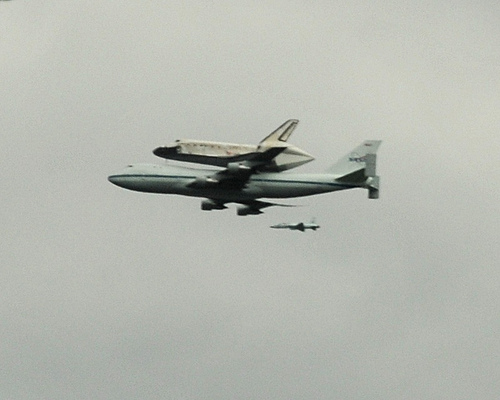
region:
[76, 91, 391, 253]
this is a plane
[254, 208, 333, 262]
this is a smaller plane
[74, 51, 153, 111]
the sky is grey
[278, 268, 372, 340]
the sky is grey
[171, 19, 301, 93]
the sky is grey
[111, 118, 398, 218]
this is a plane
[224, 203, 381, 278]
this is a plane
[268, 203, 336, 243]
this plane is a small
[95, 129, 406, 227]
this plane is a big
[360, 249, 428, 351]
the sky is gray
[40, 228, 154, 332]
the sky is gray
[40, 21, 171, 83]
the sky is gray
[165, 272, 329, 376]
the sky is gray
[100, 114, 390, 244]
3 planes in the air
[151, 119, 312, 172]
white and black plane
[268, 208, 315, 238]
small plane in the distance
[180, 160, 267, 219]
engines on the largest plane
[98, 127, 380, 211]
blue and gray plane with smaller plane on top of it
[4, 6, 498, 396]
clear skies the planes are flying in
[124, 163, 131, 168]
cockpit windows of largest plane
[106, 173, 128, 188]
nose of the largest plane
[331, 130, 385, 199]
tail wings of the largest plane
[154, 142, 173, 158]
black nose of white and black plane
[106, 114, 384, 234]
several vehicles in air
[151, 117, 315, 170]
nasa space shuttle is black and white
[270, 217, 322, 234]
jet flying escort beside planes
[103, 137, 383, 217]
large airplane under shuttle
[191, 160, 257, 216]
four turbine engines on plane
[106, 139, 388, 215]
large plane is grey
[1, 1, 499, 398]
sky is overcast and grey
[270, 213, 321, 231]
airforce is light gray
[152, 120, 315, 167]
space shuttle is black and white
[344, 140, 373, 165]
nasa insignia on tail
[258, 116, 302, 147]
white part on plane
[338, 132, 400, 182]
white part on plane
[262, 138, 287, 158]
white part on plane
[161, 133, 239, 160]
white part on plane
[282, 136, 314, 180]
white part on plane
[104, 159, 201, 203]
white part on plane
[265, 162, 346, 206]
white part on plane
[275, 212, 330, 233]
white part on plane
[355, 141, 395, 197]
tail of the airplane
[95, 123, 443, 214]
the airplanes are flying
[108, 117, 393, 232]
the airplanes are in the sky